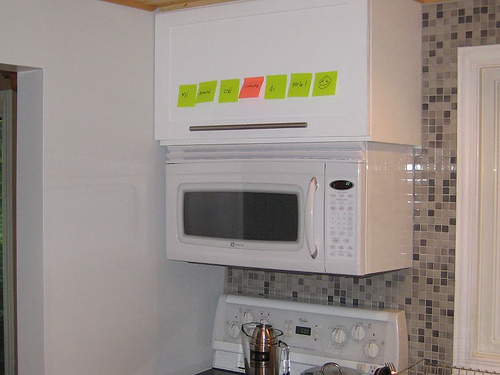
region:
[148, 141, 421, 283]
A white microwave.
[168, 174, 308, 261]
Glass door on microwave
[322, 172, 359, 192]
Display panel on microwave.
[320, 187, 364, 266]
Control panel on front of microwave.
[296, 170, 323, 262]
White handle on microwave.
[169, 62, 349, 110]
Seven post its stuck on cabinet.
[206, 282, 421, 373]
White top of stove.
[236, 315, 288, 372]
A glass measuring cup.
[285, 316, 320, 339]
Display panel on stove.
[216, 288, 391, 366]
Controls knobs for stove.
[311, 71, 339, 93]
a green sticky note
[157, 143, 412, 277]
a white over the range microwave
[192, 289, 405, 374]
part of a white oven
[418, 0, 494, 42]
gray colored wall tile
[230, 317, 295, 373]
a tall glass cup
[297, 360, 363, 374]
part of a gray covered lid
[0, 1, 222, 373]
the side of a white wall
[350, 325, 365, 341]
a small oven knob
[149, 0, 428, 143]
a white wooden cabinet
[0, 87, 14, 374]
part of a white door frame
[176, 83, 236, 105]
Three green Post It Notes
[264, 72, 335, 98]
Three green Post It Notes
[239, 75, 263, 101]
A red Post it Note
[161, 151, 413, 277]
A white oven range mounted mirowave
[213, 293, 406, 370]
Kitchen oven control panel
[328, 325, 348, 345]
Kitchen oven control knob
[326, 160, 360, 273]
Microwave control panel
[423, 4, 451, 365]
Kitchen backsplash tiles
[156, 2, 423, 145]
A white kitchen cabinet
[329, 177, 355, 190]
A microwave's lcd display panel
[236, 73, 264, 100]
pink square post-it note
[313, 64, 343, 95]
this is a smily face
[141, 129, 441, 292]
this is a microwave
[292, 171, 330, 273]
a white microwave handle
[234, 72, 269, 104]
a pink sticky note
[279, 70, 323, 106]
a green sticky note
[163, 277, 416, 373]
this is an oven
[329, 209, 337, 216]
this is the number 1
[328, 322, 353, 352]
this is a stove dial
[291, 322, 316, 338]
a black oven screen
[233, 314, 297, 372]
this is a pitcher